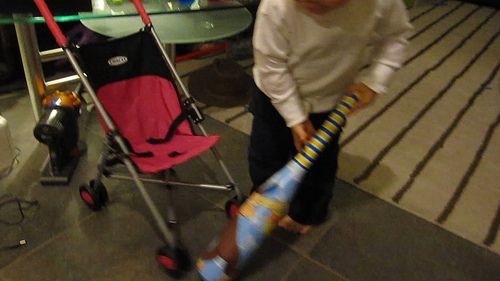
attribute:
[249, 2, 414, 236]
child — holding, barefoot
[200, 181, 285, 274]
charactors — cartoon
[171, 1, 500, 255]
rug — striped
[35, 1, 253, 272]
stroller — unoccupied, red, black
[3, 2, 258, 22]
table — glass, frosted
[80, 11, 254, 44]
chair — clear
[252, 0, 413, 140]
shirt — white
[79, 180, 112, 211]
wheels — red, black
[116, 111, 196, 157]
strap — black